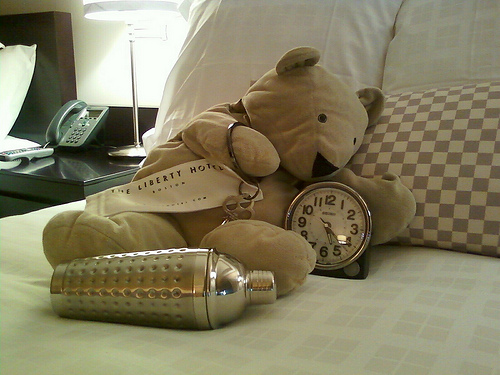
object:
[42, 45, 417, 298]
doll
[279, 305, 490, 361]
sheet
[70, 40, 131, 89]
wall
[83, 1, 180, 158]
lamp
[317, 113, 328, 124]
dot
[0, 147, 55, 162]
tv remote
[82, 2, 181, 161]
white lamp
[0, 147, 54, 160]
remote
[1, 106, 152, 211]
table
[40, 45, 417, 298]
small doll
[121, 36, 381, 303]
bear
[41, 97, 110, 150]
telephone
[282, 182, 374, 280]
clock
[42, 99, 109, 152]
phone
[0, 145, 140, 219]
night stand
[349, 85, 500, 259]
pillow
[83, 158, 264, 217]
label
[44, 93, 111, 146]
telephone system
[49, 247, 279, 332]
drink shaker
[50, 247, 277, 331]
bottle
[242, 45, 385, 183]
head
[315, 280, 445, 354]
bed